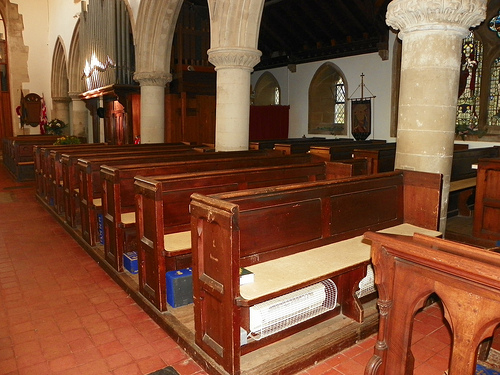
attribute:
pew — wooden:
[191, 166, 411, 355]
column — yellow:
[206, 1, 263, 151]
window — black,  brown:
[308, 61, 349, 141]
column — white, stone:
[391, 30, 473, 238]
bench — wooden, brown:
[3, 128, 497, 368]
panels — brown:
[223, 169, 405, 267]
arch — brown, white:
[250, 77, 285, 106]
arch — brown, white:
[310, 63, 343, 135]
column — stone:
[382, 2, 489, 234]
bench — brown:
[99, 144, 336, 274]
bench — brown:
[32, 142, 132, 202]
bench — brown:
[46, 150, 220, 215]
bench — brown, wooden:
[341, 139, 385, 178]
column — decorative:
[380, 1, 463, 239]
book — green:
[227, 263, 258, 296]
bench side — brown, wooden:
[37, 145, 49, 202]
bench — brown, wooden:
[181, 162, 449, 364]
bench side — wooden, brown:
[324, 162, 349, 180]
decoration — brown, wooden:
[356, 223, 498, 371]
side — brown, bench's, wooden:
[190, 192, 241, 374]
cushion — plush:
[230, 224, 442, 300]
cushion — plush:
[148, 222, 197, 251]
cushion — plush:
[117, 208, 137, 221]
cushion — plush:
[91, 194, 104, 209]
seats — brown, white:
[29, 136, 496, 374]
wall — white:
[255, 42, 395, 138]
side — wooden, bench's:
[188, 193, 238, 367]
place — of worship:
[16, 67, 423, 302]